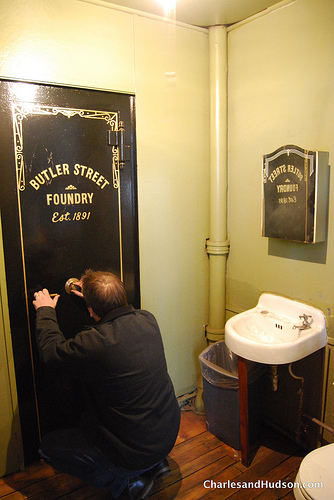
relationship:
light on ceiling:
[159, 3, 185, 24] [193, 5, 236, 23]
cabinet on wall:
[258, 143, 323, 253] [236, 32, 319, 118]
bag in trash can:
[190, 331, 279, 389] [196, 329, 270, 453]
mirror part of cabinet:
[261, 143, 315, 242] [259, 143, 329, 246]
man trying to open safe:
[33, 267, 184, 499] [2, 71, 146, 486]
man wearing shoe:
[33, 267, 184, 499] [105, 470, 158, 498]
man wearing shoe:
[33, 267, 184, 499] [148, 454, 173, 479]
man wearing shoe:
[33, 267, 184, 499] [148, 456, 174, 484]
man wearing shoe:
[33, 267, 184, 499] [122, 466, 154, 496]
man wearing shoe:
[15, 242, 186, 497] [110, 466, 159, 497]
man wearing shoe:
[15, 242, 186, 497] [148, 455, 172, 482]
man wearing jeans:
[15, 242, 186, 497] [39, 443, 164, 498]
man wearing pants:
[33, 267, 184, 499] [21, 423, 180, 491]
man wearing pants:
[33, 267, 184, 499] [31, 431, 184, 498]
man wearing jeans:
[33, 267, 184, 499] [23, 420, 188, 498]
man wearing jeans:
[33, 267, 184, 499] [24, 415, 203, 490]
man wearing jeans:
[33, 267, 184, 499] [32, 445, 191, 496]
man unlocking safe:
[33, 267, 184, 499] [2, 71, 146, 486]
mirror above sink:
[249, 130, 332, 265] [209, 286, 330, 379]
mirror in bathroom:
[261, 143, 315, 242] [1, 1, 322, 498]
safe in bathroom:
[0, 73, 166, 451] [1, 1, 322, 498]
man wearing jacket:
[33, 267, 184, 499] [31, 304, 184, 463]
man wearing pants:
[33, 267, 184, 499] [36, 421, 162, 495]